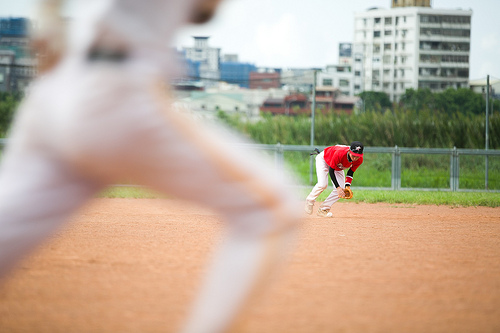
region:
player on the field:
[293, 129, 385, 236]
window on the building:
[418, 13, 425, 25]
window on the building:
[401, 16, 409, 27]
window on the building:
[383, 16, 392, 25]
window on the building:
[370, 16, 378, 26]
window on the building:
[382, 41, 390, 51]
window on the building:
[381, 68, 388, 78]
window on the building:
[384, 71, 392, 79]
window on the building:
[386, 79, 399, 89]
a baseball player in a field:
[304, 142, 364, 219]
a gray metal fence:
[258, 141, 498, 192]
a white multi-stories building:
[356, 9, 471, 91]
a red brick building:
[265, 93, 353, 118]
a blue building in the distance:
[220, 61, 253, 85]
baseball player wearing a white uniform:
[3, 1, 300, 331]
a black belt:
[86, 45, 126, 63]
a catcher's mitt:
[340, 185, 354, 200]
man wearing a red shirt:
[324, 144, 363, 176]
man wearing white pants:
[308, 150, 347, 213]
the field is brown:
[312, 202, 424, 291]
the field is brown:
[358, 229, 432, 306]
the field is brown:
[352, 250, 415, 327]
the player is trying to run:
[10, 8, 297, 320]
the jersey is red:
[312, 123, 364, 181]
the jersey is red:
[319, 138, 372, 194]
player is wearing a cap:
[330, 128, 378, 188]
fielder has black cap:
[351, 146, 379, 176]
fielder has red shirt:
[319, 144, 386, 170]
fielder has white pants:
[314, 156, 347, 204]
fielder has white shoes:
[298, 201, 343, 221]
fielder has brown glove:
[331, 188, 360, 206]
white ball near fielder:
[326, 201, 353, 216]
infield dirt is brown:
[298, 216, 431, 321]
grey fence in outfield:
[331, 114, 499, 206]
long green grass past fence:
[221, 106, 488, 136]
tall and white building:
[331, 3, 456, 100]